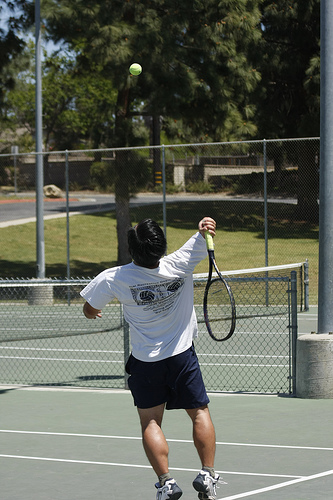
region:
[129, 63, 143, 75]
the tennis ball is in the air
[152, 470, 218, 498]
man has tennis shoes on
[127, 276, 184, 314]
black print on the shirt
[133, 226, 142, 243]
part in the man's hair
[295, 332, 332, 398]
concrete base for the pole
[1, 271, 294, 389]
metal chain link fence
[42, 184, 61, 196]
large white rock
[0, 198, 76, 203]
the curb is painted red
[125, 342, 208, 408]
dark blue athletic shorts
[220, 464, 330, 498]
white boundary line on the court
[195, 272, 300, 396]
part of a chain-link fence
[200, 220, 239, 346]
tennis racket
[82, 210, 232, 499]
man playing tennis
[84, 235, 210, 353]
white t-shirt printed with a black image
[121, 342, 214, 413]
navy blue shorts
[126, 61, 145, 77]
tennis ball in the air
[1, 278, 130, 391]
part of a chain-link fence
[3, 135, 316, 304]
high fence surrounding a tennis court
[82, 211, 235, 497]
man preparing to hit a tennis ball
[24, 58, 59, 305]
light pole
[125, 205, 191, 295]
the head of a man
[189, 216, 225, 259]
the hand of a man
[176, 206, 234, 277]
the arm of a man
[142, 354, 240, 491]
the legs of a man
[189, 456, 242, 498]
the foot of a man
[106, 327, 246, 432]
a man wearing shorts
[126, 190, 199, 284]
the back of a man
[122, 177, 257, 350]
a man holding a tennis racket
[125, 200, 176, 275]
the hair of a man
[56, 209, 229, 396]
a man wearing a shirt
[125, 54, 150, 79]
Yellow tennis ball in the sky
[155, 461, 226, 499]
Black and white tennis shoes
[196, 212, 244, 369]
Black and white tennis racket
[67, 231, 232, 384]
White shirt on man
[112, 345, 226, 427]
Blue shorts on tennis player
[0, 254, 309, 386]
Black and white tennis net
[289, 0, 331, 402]
Grey cement pole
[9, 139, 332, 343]
Grey chain link fence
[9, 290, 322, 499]
White lines on tennis court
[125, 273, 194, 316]
Black writing on t shirt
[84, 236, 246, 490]
person playing tennis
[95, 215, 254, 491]
person ready to hit tennis ball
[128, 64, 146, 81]
yellow tennis ball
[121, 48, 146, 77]
yellow tennis ball mid air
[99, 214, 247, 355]
person holding tennis racket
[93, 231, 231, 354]
person wearing white shirt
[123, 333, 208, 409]
person wearing black shorts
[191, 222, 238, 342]
tennis racket is in right hand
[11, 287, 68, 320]
chain link fece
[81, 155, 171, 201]
tall chain linked fence